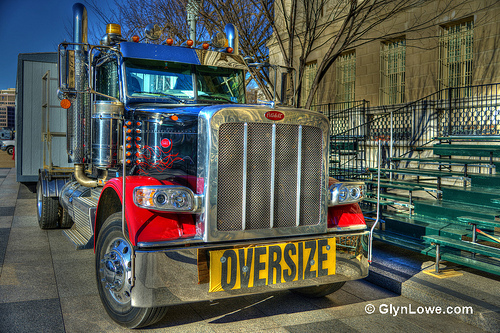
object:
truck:
[14, 3, 372, 329]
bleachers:
[372, 134, 499, 264]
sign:
[209, 238, 336, 294]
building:
[269, 0, 499, 141]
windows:
[380, 16, 472, 104]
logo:
[264, 110, 285, 120]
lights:
[132, 35, 233, 53]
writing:
[219, 238, 330, 291]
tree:
[247, 0, 353, 106]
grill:
[216, 122, 321, 232]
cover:
[93, 176, 198, 254]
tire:
[94, 211, 168, 329]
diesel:
[69, 99, 198, 187]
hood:
[123, 102, 267, 114]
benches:
[368, 167, 478, 218]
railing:
[338, 112, 428, 155]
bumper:
[129, 223, 368, 309]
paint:
[132, 214, 182, 236]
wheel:
[93, 210, 166, 330]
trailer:
[16, 51, 68, 181]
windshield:
[124, 64, 244, 100]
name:
[364, 303, 473, 317]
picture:
[0, 0, 490, 331]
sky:
[15, 11, 187, 45]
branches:
[243, 10, 275, 54]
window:
[96, 60, 118, 100]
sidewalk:
[383, 264, 498, 305]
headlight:
[133, 185, 197, 212]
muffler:
[74, 164, 98, 187]